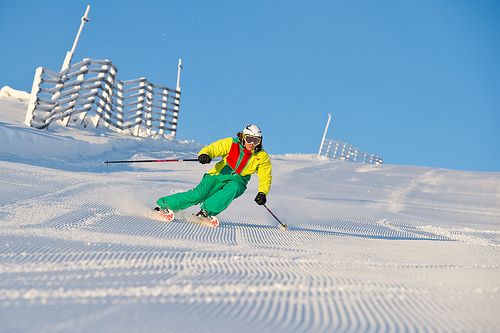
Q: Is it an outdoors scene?
A: Yes, it is outdoors.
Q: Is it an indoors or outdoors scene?
A: It is outdoors.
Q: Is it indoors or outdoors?
A: It is outdoors.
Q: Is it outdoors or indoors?
A: It is outdoors.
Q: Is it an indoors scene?
A: No, it is outdoors.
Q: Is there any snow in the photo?
A: Yes, there is snow.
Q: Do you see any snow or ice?
A: Yes, there is snow.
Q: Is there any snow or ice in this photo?
A: Yes, there is snow.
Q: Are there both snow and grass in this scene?
A: No, there is snow but no grass.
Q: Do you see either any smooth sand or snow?
A: Yes, there is smooth snow.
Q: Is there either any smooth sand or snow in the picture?
A: Yes, there is smooth snow.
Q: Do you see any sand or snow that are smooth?
A: Yes, the snow is smooth.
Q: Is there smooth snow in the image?
A: Yes, there is smooth snow.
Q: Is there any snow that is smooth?
A: Yes, there is snow that is smooth.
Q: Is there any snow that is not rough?
A: Yes, there is smooth snow.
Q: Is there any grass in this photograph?
A: No, there is no grass.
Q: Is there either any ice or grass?
A: No, there are no grass or ice.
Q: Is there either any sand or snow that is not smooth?
A: No, there is snow but it is smooth.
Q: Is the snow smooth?
A: Yes, the snow is smooth.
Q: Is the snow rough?
A: No, the snow is smooth.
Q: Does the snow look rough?
A: No, the snow is smooth.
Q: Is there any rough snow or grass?
A: No, there is snow but it is smooth.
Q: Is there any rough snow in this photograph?
A: No, there is snow but it is smooth.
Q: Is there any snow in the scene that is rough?
A: No, there is snow but it is smooth.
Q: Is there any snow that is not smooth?
A: No, there is snow but it is smooth.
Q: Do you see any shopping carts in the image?
A: No, there are no shopping carts.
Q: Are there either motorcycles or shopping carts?
A: No, there are no shopping carts or motorcycles.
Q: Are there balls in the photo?
A: No, there are no balls.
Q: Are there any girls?
A: No, there are no girls.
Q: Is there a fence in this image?
A: Yes, there is a fence.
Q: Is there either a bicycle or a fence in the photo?
A: Yes, there is a fence.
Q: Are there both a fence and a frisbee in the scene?
A: No, there is a fence but no frisbees.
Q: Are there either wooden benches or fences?
A: Yes, there is a wood fence.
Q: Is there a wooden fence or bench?
A: Yes, there is a wood fence.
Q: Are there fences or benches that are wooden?
A: Yes, the fence is wooden.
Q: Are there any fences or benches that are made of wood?
A: Yes, the fence is made of wood.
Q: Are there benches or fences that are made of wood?
A: Yes, the fence is made of wood.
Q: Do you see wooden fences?
A: Yes, there is a wood fence.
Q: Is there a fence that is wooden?
A: Yes, there is a fence that is wooden.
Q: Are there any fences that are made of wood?
A: Yes, there is a fence that is made of wood.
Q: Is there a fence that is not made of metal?
A: Yes, there is a fence that is made of wood.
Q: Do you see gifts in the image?
A: No, there are no gifts.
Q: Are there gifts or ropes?
A: No, there are no gifts or ropes.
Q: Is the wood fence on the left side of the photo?
A: Yes, the fence is on the left of the image.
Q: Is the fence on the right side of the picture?
A: No, the fence is on the left of the image.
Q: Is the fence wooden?
A: Yes, the fence is wooden.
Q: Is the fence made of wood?
A: Yes, the fence is made of wood.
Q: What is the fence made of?
A: The fence is made of wood.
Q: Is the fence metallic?
A: No, the fence is wooden.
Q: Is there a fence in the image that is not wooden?
A: No, there is a fence but it is wooden.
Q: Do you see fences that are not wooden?
A: No, there is a fence but it is wooden.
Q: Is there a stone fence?
A: No, there is a fence but it is made of wood.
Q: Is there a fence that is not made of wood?
A: No, there is a fence but it is made of wood.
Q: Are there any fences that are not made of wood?
A: No, there is a fence but it is made of wood.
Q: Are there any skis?
A: Yes, there are skis.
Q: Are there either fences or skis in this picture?
A: Yes, there are skis.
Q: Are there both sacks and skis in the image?
A: No, there are skis but no sacks.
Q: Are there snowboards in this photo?
A: No, there are no snowboards.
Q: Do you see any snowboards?
A: No, there are no snowboards.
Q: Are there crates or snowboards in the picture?
A: No, there are no snowboards or crates.